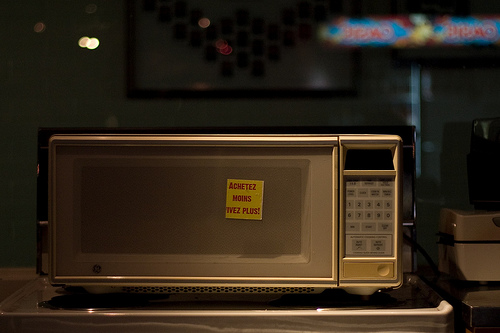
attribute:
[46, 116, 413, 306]
microwave — beige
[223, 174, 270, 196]
word — plus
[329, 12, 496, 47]
sign — blue, red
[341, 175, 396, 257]
buttons — white, gray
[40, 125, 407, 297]
microwave — countertop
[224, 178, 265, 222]
sign — yellow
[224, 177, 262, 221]
sticker — yellow, red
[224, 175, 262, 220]
print — red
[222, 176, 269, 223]
sign — yellow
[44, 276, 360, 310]
underside — ventilated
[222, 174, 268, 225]
lettering — red